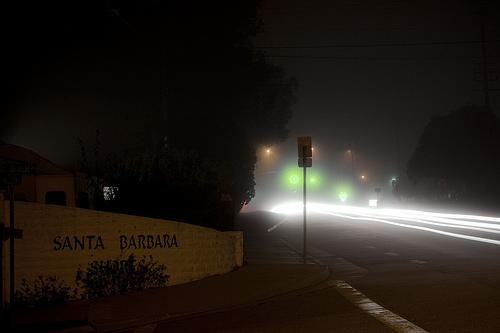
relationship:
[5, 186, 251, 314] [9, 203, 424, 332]
sign on curb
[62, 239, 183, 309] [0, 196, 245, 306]
bush growing near wall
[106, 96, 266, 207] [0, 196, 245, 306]
trees near wall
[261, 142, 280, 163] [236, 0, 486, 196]
yellow light on sky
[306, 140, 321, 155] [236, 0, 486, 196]
yellow light on sky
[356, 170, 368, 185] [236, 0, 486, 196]
yellow light on sky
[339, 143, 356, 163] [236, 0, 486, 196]
yellow light on sky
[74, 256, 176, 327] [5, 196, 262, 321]
plants next to wall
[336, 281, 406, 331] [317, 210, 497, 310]
line painted on street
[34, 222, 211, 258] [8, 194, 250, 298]
sant barbara on wall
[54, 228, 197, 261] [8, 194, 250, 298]
name on wall